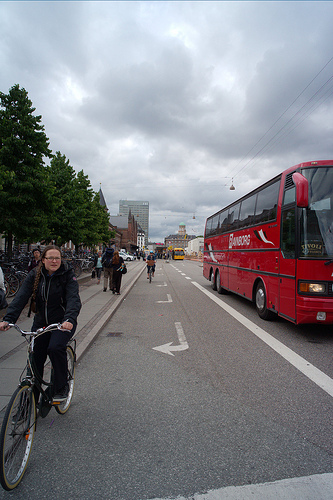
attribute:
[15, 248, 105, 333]
woman — looking, here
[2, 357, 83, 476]
bike — close, here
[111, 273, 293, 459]
road — black, grey, paved, close, here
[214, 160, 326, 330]
bus — red, long, huge, moving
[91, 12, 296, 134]
sky — dark, grey, cloudy